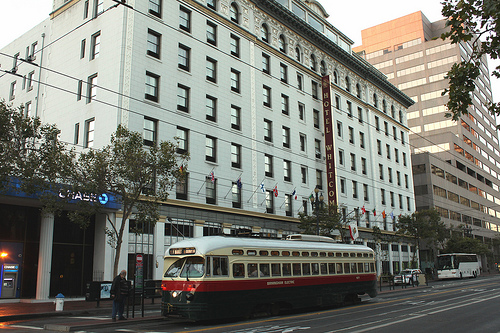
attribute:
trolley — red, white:
[177, 232, 395, 320]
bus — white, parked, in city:
[441, 244, 481, 282]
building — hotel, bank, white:
[21, 14, 419, 288]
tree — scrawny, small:
[56, 122, 154, 301]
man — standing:
[115, 263, 133, 315]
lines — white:
[323, 290, 477, 330]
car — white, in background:
[388, 259, 416, 291]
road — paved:
[392, 286, 499, 326]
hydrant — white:
[43, 287, 73, 313]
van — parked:
[398, 267, 424, 281]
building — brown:
[356, 28, 498, 245]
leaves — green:
[77, 130, 169, 204]